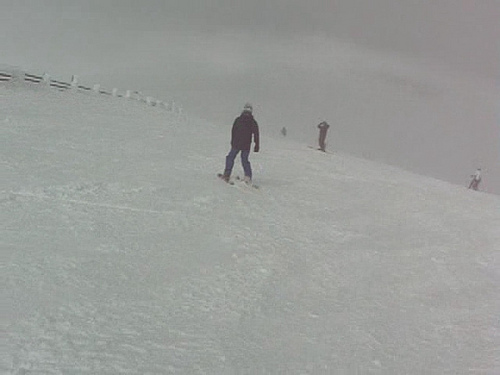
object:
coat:
[228, 112, 260, 151]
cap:
[242, 102, 256, 110]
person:
[217, 102, 261, 182]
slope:
[0, 80, 499, 374]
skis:
[234, 175, 259, 192]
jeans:
[221, 149, 252, 178]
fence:
[0, 63, 184, 117]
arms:
[250, 119, 260, 146]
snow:
[7, 66, 53, 90]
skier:
[466, 167, 483, 192]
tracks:
[87, 193, 168, 221]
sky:
[0, 0, 499, 196]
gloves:
[251, 144, 260, 154]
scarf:
[238, 110, 253, 122]